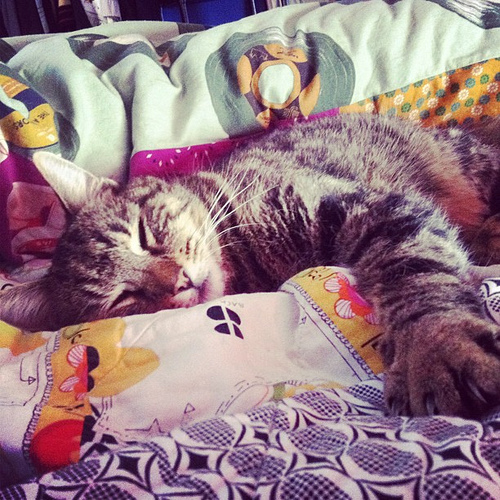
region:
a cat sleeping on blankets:
[2, 110, 498, 423]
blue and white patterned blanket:
[0, 373, 497, 498]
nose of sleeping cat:
[155, 265, 193, 294]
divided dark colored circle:
[207, 303, 246, 340]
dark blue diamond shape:
[113, 450, 145, 483]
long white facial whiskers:
[178, 170, 284, 261]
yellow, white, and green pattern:
[344, 55, 499, 132]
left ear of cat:
[29, 149, 106, 218]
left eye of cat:
[132, 208, 149, 253]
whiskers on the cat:
[196, 166, 281, 258]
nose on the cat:
[156, 256, 197, 306]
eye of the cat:
[98, 273, 145, 315]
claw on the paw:
[455, 370, 498, 411]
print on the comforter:
[21, 356, 358, 495]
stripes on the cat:
[63, 219, 123, 326]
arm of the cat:
[366, 220, 478, 460]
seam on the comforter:
[66, 309, 157, 411]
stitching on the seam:
[277, 307, 317, 391]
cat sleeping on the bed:
[52, 139, 480, 398]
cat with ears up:
[2, 135, 486, 390]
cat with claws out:
[26, 122, 478, 407]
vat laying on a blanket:
[2, 38, 484, 441]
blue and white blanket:
[67, 374, 482, 499]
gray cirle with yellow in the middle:
[203, 16, 361, 130]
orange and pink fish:
[321, 265, 372, 333]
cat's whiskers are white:
[19, 127, 477, 397]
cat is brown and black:
[40, 100, 470, 403]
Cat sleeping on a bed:
[17, 111, 486, 400]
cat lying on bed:
[38, 137, 488, 405]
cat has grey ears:
[16, 142, 81, 336]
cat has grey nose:
[165, 263, 182, 292]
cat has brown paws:
[353, 226, 496, 424]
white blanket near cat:
[84, 289, 424, 410]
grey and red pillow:
[118, 12, 373, 158]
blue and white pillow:
[235, 390, 377, 498]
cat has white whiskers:
[155, 141, 255, 298]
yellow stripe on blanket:
[326, 72, 496, 125]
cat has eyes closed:
[114, 201, 164, 314]